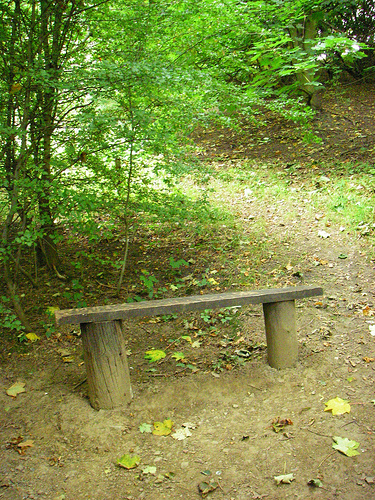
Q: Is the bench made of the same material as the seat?
A: Yes, both the bench and the seat are made of wood.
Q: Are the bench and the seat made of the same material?
A: Yes, both the bench and the seat are made of wood.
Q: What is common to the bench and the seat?
A: The material, both the bench and the seat are wooden.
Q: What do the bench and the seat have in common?
A: The material, both the bench and the seat are wooden.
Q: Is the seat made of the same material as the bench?
A: Yes, both the seat and the bench are made of wood.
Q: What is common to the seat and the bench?
A: The material, both the seat and the bench are wooden.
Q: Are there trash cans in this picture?
A: No, there are no trash cans.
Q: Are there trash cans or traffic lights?
A: No, there are no trash cans or traffic lights.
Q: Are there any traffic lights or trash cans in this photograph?
A: No, there are no trash cans or traffic lights.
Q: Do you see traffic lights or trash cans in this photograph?
A: No, there are no trash cans or traffic lights.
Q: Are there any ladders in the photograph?
A: No, there are no ladders.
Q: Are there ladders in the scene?
A: No, there are no ladders.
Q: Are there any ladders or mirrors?
A: No, there are no ladders or mirrors.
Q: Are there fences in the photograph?
A: No, there are no fences.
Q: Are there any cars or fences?
A: No, there are no fences or cars.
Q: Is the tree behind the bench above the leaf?
A: Yes, the tree is behind the bench.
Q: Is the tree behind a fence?
A: No, the tree is behind the bench.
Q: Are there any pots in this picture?
A: No, there are no pots.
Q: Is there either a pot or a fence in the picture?
A: No, there are no pots or fences.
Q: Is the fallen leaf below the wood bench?
A: Yes, the leaf is below the bench.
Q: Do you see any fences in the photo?
A: No, there are no fences.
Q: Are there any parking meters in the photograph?
A: No, there are no parking meters.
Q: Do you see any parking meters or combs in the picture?
A: No, there are no parking meters or combs.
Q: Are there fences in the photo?
A: No, there are no fences.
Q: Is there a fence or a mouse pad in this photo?
A: No, there are no fences or mouse pads.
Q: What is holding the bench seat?
A: The log is holding the seat.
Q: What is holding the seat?
A: The log is holding the seat.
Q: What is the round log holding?
A: The log is holding the seat.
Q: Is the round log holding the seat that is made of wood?
A: Yes, the log is holding the seat.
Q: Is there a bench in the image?
A: Yes, there is a bench.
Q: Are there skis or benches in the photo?
A: Yes, there is a bench.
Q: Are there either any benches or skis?
A: Yes, there is a bench.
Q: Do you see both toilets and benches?
A: No, there is a bench but no toilets.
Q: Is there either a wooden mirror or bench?
A: Yes, there is a wood bench.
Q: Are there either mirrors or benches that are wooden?
A: Yes, the bench is wooden.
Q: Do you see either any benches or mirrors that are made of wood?
A: Yes, the bench is made of wood.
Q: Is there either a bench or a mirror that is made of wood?
A: Yes, the bench is made of wood.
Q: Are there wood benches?
A: Yes, there is a wood bench.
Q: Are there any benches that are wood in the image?
A: Yes, there is a wood bench.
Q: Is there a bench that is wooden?
A: Yes, there is a bench that is wooden.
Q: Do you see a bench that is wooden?
A: Yes, there is a bench that is wooden.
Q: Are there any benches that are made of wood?
A: Yes, there is a bench that is made of wood.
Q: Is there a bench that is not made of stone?
A: Yes, there is a bench that is made of wood.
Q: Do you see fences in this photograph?
A: No, there are no fences.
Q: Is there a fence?
A: No, there are no fences.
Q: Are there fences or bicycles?
A: No, there are no fences or bicycles.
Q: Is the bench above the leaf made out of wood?
A: Yes, the bench is made of wood.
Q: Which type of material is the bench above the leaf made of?
A: The bench is made of wood.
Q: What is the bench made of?
A: The bench is made of wood.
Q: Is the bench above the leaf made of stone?
A: No, the bench is made of wood.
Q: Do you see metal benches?
A: No, there is a bench but it is made of wood.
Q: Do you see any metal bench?
A: No, there is a bench but it is made of wood.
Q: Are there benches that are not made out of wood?
A: No, there is a bench but it is made of wood.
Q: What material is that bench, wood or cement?
A: The bench is made of wood.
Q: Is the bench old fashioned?
A: Yes, the bench is old fashioned.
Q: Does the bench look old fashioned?
A: Yes, the bench is old fashioned.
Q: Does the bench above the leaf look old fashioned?
A: Yes, the bench is old fashioned.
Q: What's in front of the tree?
A: The bench is in front of the tree.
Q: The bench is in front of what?
A: The bench is in front of the tree.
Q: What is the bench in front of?
A: The bench is in front of the tree.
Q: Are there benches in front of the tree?
A: Yes, there is a bench in front of the tree.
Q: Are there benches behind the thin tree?
A: No, the bench is in front of the tree.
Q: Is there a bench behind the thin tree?
A: No, the bench is in front of the tree.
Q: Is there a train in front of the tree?
A: No, there is a bench in front of the tree.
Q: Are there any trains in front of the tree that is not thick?
A: No, there is a bench in front of the tree.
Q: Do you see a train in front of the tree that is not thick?
A: No, there is a bench in front of the tree.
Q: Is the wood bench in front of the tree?
A: Yes, the bench is in front of the tree.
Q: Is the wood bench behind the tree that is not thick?
A: No, the bench is in front of the tree.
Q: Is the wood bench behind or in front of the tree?
A: The bench is in front of the tree.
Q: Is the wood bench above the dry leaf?
A: Yes, the bench is above the leaf.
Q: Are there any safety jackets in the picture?
A: No, there are no safety jackets.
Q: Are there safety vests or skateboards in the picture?
A: No, there are no safety vests or skateboards.